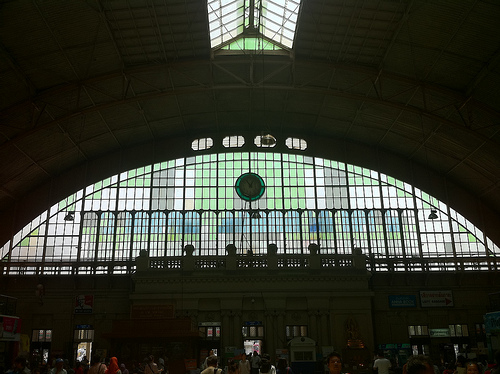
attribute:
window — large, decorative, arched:
[5, 152, 499, 285]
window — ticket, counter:
[8, 107, 499, 296]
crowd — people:
[5, 334, 498, 371]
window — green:
[216, 33, 283, 53]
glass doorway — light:
[49, 169, 453, 309]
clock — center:
[234, 171, 267, 203]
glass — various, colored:
[0, 132, 498, 272]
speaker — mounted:
[136, 247, 152, 258]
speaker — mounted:
[180, 238, 197, 256]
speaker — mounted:
[222, 242, 239, 254]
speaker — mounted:
[262, 242, 279, 254]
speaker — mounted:
[306, 242, 320, 253]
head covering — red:
[108, 355, 118, 367]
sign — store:
[3, 317, 23, 342]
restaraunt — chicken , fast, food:
[121, 248, 386, 371]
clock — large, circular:
[231, 167, 270, 201]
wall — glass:
[20, 132, 488, 266]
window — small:
[285, 137, 307, 150]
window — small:
[255, 135, 276, 147]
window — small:
[221, 135, 244, 147]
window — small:
[192, 137, 213, 149]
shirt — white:
[373, 351, 393, 366]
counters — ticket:
[17, 310, 488, 355]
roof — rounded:
[7, 4, 494, 93]